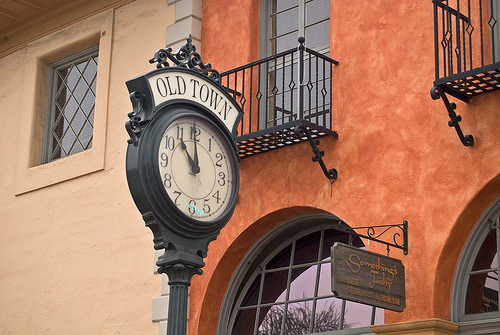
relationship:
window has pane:
[39, 46, 100, 161] [68, 108, 89, 137]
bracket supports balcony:
[429, 85, 475, 148] [429, 2, 499, 103]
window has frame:
[467, 226, 499, 311] [450, 197, 500, 322]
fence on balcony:
[220, 36, 332, 133] [215, 35, 334, 159]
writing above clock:
[155, 73, 232, 121] [155, 110, 238, 227]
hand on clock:
[179, 136, 194, 167] [155, 110, 238, 227]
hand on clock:
[191, 118, 200, 162] [155, 110, 238, 227]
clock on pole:
[155, 110, 238, 227] [156, 247, 205, 333]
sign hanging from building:
[329, 241, 409, 312] [188, 0, 500, 334]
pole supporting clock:
[156, 247, 205, 333] [155, 110, 238, 227]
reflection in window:
[257, 248, 385, 329] [229, 226, 384, 332]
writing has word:
[155, 73, 232, 121] [155, 75, 190, 100]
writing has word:
[155, 73, 232, 121] [188, 74, 233, 121]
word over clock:
[155, 75, 190, 100] [155, 110, 238, 227]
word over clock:
[188, 74, 233, 121] [155, 110, 238, 227]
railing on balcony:
[218, 45, 341, 77] [215, 35, 334, 159]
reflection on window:
[257, 248, 385, 329] [229, 226, 384, 332]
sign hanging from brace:
[329, 241, 409, 312] [338, 217, 411, 254]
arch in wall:
[195, 205, 389, 334] [188, 0, 500, 334]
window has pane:
[39, 46, 100, 161] [62, 63, 83, 93]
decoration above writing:
[147, 34, 222, 87] [155, 73, 232, 121]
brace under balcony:
[290, 123, 338, 181] [215, 35, 334, 159]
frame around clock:
[124, 104, 240, 256] [155, 110, 238, 227]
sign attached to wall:
[329, 241, 409, 312] [188, 0, 500, 334]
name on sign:
[340, 251, 400, 293] [329, 241, 409, 312]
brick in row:
[173, 1, 201, 20] [151, 1, 204, 331]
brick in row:
[151, 295, 190, 320] [151, 1, 204, 331]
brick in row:
[165, 17, 205, 45] [151, 1, 204, 331]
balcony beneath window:
[215, 35, 334, 159] [268, 0, 331, 126]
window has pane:
[229, 226, 384, 332] [258, 267, 291, 308]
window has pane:
[229, 226, 384, 332] [283, 296, 317, 334]